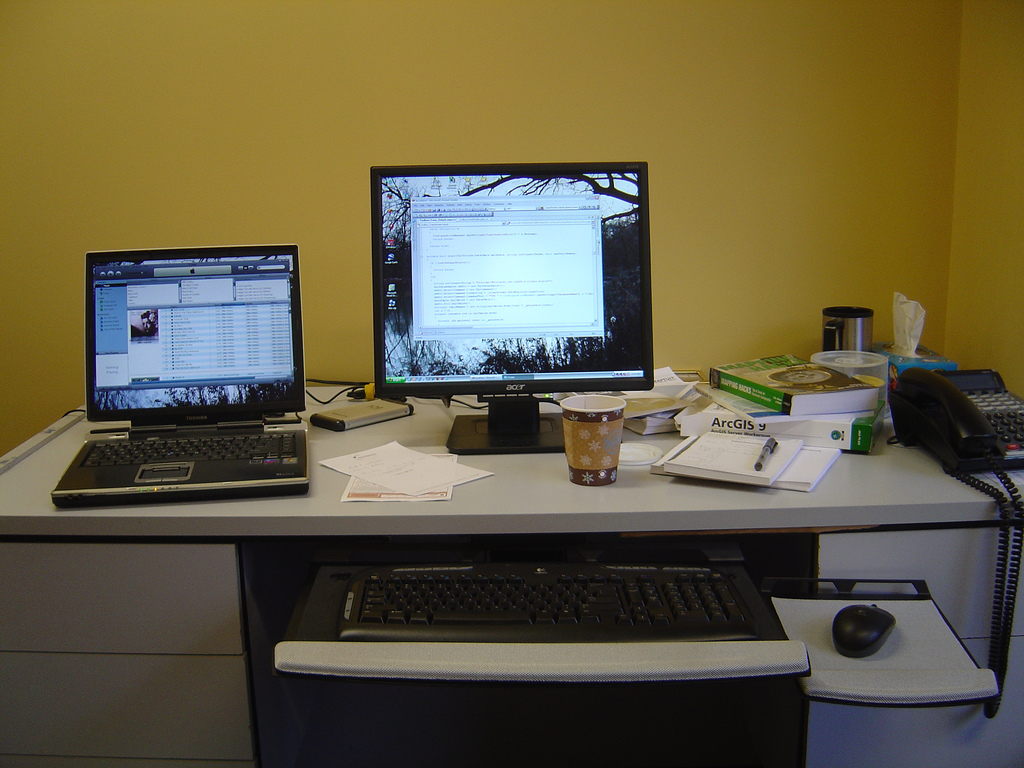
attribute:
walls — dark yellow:
[5, 11, 1019, 413]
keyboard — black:
[269, 546, 814, 680]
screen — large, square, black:
[356, 156, 657, 401]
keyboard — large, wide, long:
[332, 556, 786, 649]